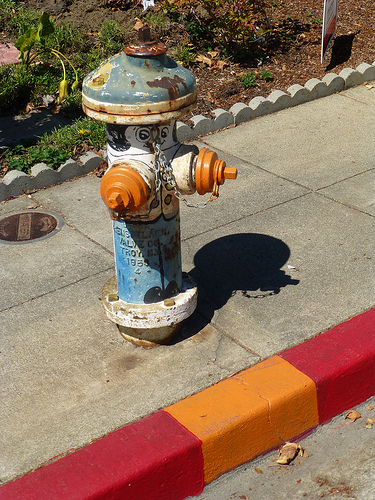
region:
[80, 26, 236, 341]
old fire hydrant that has been decorated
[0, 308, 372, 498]
a red and yellow painted curb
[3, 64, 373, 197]
white concrete scalloped edging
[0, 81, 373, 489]
a concrete sidewalk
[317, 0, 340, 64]
a white cardboard sign stuck in the garden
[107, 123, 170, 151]
face drawn on fire hydrant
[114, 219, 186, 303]
blue "pants" on fire hydrant with black "shoes"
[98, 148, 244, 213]
two yellow fire hose hook-ups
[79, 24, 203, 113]
rusty blue hydrant cap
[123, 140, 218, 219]
two chains on the fire hydrant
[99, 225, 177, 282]
words on the hydrant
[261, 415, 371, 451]
litter on the ground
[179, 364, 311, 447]
orange in the middle of red curb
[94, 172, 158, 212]
orange on the locks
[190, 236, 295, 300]
shadow on the ground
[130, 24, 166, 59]
rust on the top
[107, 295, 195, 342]
white on bottom of hydrant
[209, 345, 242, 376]
crack in the sidewalk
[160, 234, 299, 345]
the shadow of the hydrant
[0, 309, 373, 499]
a red and yellow paints on pavement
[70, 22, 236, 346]
a very funny hydrant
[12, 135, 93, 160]
some grass on the ground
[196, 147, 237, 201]
a metal yellow cap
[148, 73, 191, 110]
a rusty part of the hydrant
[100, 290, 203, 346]
this part of the hydrant is white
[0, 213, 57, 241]
a round metal cap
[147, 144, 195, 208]
a small silver chain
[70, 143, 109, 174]
some dry leaves on the ground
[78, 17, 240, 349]
fire hydrant on the sidewalk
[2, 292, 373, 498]
red and yellow paint on the sidewalk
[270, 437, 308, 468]
leaf along the curb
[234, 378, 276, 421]
crack in the curb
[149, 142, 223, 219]
chain on the hydrant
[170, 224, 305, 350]
shadow from the fire hydrant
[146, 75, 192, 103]
rust on the top of the hydrant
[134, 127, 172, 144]
eyes drawn on the hydrant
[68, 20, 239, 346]
yellow, blue, and white fire hydrant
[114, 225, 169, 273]
engraving on the side of the hydrant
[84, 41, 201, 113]
light blue cap on hydrant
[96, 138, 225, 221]
orange sides of hydrant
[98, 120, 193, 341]
white and blue hydrant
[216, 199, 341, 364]
sidewalk is light brown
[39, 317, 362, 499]
red and orange curb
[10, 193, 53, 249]
brown pipe behind hydrant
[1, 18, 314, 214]
small round stones for wall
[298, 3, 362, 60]
small sign stuck in dirt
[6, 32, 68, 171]
green grass behind dividers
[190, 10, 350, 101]
brown dirt behind dividers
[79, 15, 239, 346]
a colorful fire hydrant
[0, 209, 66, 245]
a circle grate on the sidewalk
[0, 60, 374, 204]
a gray partition between the sidewalk and dirt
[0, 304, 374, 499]
a red and orange curb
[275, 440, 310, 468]
a leaf in the gutter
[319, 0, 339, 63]
a white and red sign